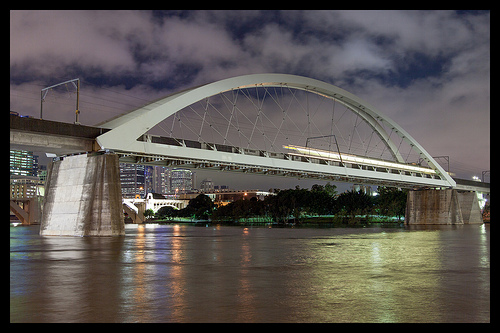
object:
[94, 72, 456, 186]
arch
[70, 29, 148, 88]
clouds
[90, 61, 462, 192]
two zebras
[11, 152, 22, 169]
buildings lit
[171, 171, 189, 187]
windows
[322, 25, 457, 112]
clouds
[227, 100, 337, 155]
wires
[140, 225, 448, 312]
water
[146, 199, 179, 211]
city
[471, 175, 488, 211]
lights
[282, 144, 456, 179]
train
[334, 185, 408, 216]
trees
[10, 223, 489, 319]
grayish water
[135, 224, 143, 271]
reflecting lights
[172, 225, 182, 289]
reflecting lights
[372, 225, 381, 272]
reflecting lights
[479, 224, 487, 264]
reflecting lights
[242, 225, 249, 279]
reflecting lights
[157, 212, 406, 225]
green lighting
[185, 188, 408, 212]
trees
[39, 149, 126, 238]
support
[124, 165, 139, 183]
windows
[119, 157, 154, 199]
building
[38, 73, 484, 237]
bridge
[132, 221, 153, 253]
lighting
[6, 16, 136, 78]
clouds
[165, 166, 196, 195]
buildings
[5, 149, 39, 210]
building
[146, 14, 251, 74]
cloud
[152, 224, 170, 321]
purple light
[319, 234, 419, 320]
light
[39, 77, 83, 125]
structure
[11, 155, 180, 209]
city lights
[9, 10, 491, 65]
sky